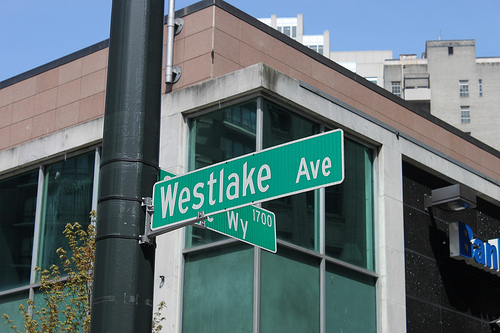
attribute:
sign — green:
[156, 123, 351, 224]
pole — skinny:
[97, 1, 155, 332]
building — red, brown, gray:
[168, 4, 491, 332]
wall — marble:
[407, 186, 447, 332]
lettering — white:
[294, 156, 332, 183]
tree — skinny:
[21, 222, 93, 333]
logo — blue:
[452, 220, 497, 270]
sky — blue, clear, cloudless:
[309, 5, 494, 31]